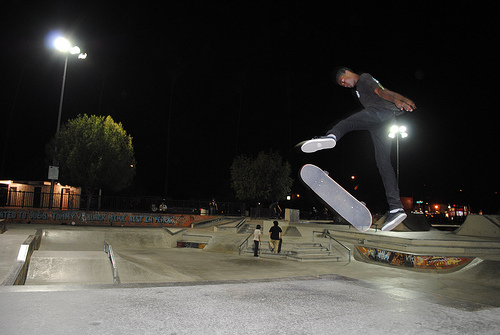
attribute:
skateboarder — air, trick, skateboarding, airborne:
[333, 73, 408, 209]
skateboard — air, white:
[301, 178, 372, 222]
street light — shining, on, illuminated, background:
[24, 17, 83, 141]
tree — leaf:
[77, 127, 125, 208]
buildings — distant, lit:
[5, 174, 99, 201]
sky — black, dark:
[217, 17, 238, 30]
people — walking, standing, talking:
[244, 206, 281, 261]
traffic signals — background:
[349, 165, 355, 180]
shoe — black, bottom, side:
[287, 136, 345, 153]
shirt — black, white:
[355, 91, 370, 97]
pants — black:
[320, 125, 403, 180]